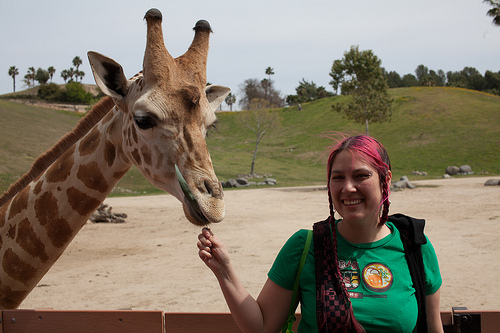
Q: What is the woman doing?
A: Feeding the giraffe.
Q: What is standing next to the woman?
A: A giraffe.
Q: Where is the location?
A: Zoo.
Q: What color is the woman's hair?
A: Pink.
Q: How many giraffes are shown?
A: One.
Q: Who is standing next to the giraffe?
A: A woman.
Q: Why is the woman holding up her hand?
A: She is feeding the giraffe.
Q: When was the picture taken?
A: Daytime.